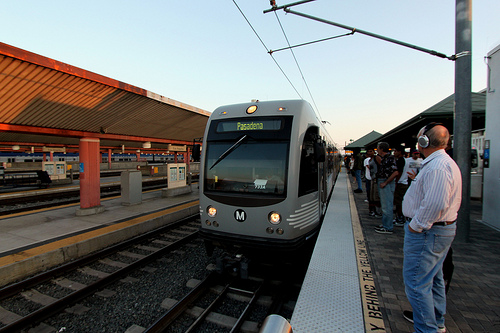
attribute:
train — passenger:
[185, 105, 338, 251]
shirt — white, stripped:
[391, 154, 451, 229]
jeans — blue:
[398, 212, 458, 331]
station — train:
[338, 40, 498, 331]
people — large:
[354, 122, 420, 227]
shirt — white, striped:
[400, 152, 464, 223]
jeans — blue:
[401, 219, 456, 330]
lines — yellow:
[1, 197, 201, 266]